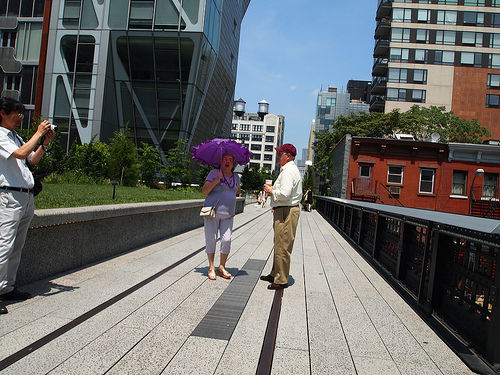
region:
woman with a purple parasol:
[195, 137, 252, 283]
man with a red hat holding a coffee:
[263, 140, 304, 290]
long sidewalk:
[0, 196, 478, 373]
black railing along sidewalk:
[314, 194, 499, 374]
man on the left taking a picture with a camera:
[0, 98, 60, 313]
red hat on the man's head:
[277, 142, 297, 158]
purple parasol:
[195, 138, 252, 168]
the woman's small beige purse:
[198, 205, 215, 218]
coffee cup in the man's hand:
[262, 179, 272, 194]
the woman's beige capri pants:
[203, 216, 230, 254]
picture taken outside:
[6, 9, 496, 366]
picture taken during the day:
[5, 9, 499, 367]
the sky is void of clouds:
[275, 28, 309, 99]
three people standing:
[6, 88, 394, 356]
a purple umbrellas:
[176, 129, 263, 169]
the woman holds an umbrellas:
[180, 116, 271, 196]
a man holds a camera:
[6, 82, 87, 224]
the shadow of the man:
[29, 270, 71, 301]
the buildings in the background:
[7, 6, 488, 188]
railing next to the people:
[325, 173, 499, 345]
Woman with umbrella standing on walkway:
[197, 152, 242, 278]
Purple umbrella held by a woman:
[190, 135, 251, 167]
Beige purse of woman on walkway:
[200, 201, 216, 217]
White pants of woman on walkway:
[203, 215, 231, 253]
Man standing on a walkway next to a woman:
[257, 143, 302, 289]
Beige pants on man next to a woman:
[267, 204, 299, 284]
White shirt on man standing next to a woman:
[268, 160, 303, 207]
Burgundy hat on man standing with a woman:
[274, 142, 298, 157]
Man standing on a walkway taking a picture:
[0, 96, 51, 312]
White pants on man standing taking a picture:
[1, 187, 36, 295]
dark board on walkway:
[176, 245, 276, 362]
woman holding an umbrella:
[179, 133, 262, 293]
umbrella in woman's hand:
[190, 131, 259, 197]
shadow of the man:
[19, 271, 76, 311]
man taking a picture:
[2, 92, 60, 312]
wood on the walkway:
[171, 194, 348, 373]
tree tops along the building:
[342, 108, 482, 154]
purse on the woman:
[190, 193, 220, 230]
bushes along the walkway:
[55, 130, 270, 195]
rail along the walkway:
[302, 185, 494, 272]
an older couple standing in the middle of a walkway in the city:
[193, 133, 313, 293]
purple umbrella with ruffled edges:
[191, 139, 255, 170]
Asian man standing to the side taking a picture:
[0, 90, 64, 326]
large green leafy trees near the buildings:
[333, 107, 492, 142]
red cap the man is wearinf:
[274, 142, 299, 154]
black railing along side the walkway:
[339, 200, 498, 356]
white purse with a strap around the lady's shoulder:
[198, 204, 217, 220]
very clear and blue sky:
[250, 16, 350, 86]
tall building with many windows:
[377, 1, 498, 115]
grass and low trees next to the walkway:
[60, 137, 197, 201]